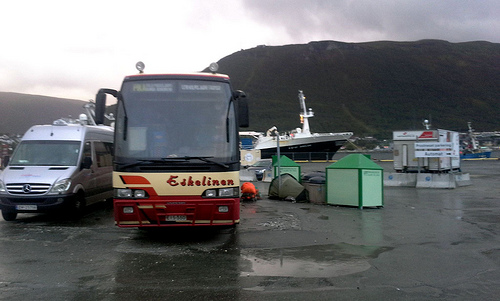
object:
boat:
[251, 88, 353, 160]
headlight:
[219, 185, 235, 197]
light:
[132, 60, 146, 75]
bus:
[93, 61, 251, 229]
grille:
[1, 182, 50, 199]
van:
[0, 119, 116, 222]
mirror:
[231, 90, 253, 129]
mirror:
[90, 91, 107, 126]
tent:
[323, 150, 381, 211]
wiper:
[186, 156, 230, 170]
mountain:
[96, 39, 500, 144]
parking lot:
[0, 157, 499, 300]